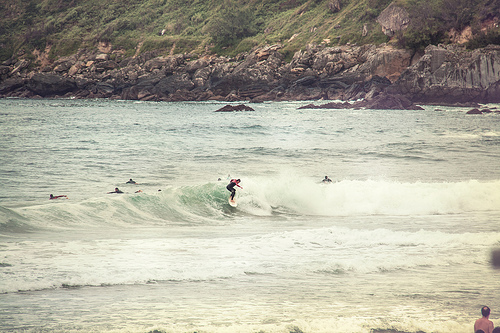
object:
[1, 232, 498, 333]
water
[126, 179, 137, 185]
person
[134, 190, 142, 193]
leg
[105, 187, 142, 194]
person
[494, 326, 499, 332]
woman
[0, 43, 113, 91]
rocks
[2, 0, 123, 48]
grass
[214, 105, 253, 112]
rock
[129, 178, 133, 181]
head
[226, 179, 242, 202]
man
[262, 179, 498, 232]
wave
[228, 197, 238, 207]
board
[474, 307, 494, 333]
man